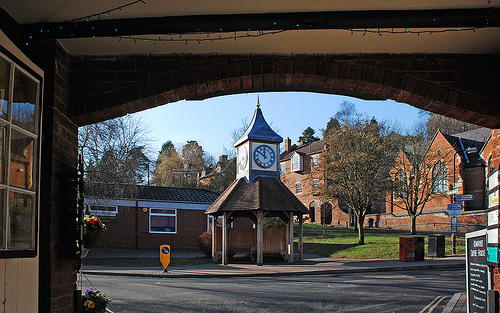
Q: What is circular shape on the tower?
A: Clock.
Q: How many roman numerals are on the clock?
A: Twelve.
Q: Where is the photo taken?
A: Street.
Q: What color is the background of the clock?
A: White.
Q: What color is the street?
A: Gray.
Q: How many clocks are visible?
A: Two.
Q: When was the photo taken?
A: 11:50.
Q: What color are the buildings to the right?
A: Red.